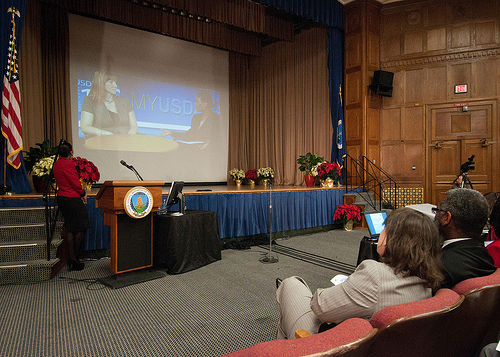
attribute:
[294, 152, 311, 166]
leaf — green 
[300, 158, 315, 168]
leaf — green 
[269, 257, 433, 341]
suit — beige 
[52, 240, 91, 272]
boots — tall , black 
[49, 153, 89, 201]
shirt — red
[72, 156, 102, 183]
flowers — red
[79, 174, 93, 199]
vase — gold 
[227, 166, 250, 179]
flowers — white 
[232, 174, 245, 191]
pot — gold 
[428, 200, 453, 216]
glasses — black 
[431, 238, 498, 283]
suit jacket — black 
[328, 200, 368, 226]
flowers — red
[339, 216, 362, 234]
vase — gold 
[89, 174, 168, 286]
podium — decorated, brown 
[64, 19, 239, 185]
screen — large , faded 